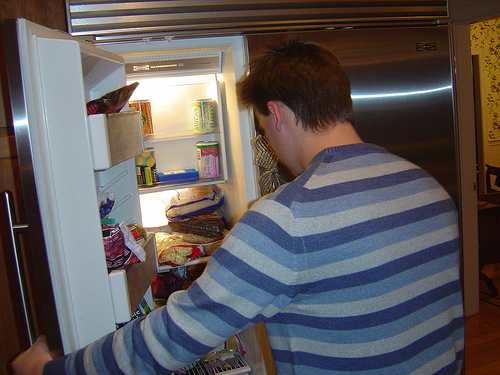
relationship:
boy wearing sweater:
[224, 59, 465, 358] [236, 163, 449, 371]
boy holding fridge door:
[224, 59, 465, 358] [1, 13, 178, 369]